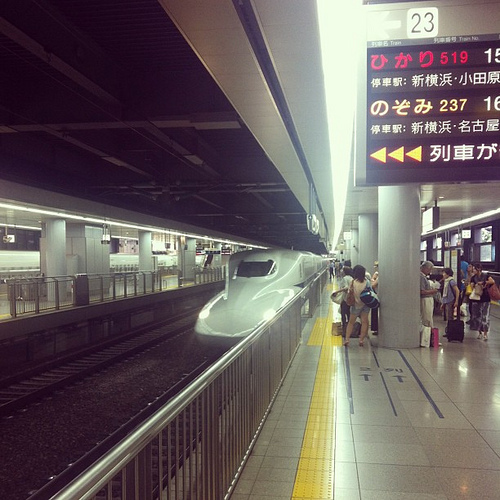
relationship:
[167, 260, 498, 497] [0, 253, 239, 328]
platform has opposite side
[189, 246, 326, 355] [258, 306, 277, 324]
train has headlight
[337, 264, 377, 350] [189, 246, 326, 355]
person waiting for train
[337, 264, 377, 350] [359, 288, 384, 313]
person has luggage